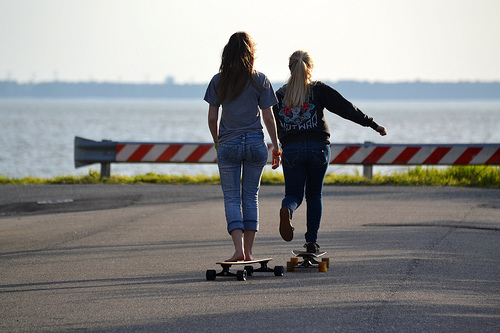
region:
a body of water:
[30, 54, 498, 189]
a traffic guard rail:
[62, 113, 494, 202]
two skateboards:
[200, 220, 410, 281]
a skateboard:
[190, 231, 284, 316]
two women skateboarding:
[190, 35, 411, 323]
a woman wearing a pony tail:
[282, 39, 350, 165]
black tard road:
[32, 182, 484, 332]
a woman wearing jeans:
[180, 25, 303, 285]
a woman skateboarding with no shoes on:
[183, 32, 280, 302]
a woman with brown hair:
[197, 42, 287, 159]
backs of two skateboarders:
[189, 29, 381, 279]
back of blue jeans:
[219, 129, 274, 240]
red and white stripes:
[360, 139, 465, 169]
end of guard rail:
[60, 129, 116, 174]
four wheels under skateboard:
[277, 255, 337, 277]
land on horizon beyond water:
[392, 74, 474, 106]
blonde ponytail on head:
[282, 59, 312, 114]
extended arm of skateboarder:
[332, 81, 396, 140]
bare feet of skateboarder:
[217, 226, 265, 267]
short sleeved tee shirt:
[204, 74, 279, 141]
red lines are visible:
[121, 131, 202, 216]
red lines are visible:
[136, 136, 191, 176]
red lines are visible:
[128, 88, 228, 183]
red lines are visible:
[102, 101, 214, 209]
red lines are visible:
[124, 124, 256, 256]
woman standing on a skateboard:
[204, 31, 280, 287]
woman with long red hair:
[199, 32, 281, 289]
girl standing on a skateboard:
[202, 27, 281, 284]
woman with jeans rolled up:
[201, 33, 278, 277]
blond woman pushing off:
[273, 45, 388, 272]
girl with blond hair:
[269, 45, 416, 281]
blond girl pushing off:
[274, 46, 389, 279]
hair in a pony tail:
[276, 44, 333, 126]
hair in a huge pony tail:
[203, 21, 269, 124]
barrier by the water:
[74, 128, 499, 183]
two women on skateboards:
[196, 26, 388, 281]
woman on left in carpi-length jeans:
[208, 125, 275, 285]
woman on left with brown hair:
[212, 31, 257, 107]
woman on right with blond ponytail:
[281, 45, 319, 117]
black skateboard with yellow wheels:
[281, 240, 333, 274]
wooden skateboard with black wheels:
[196, 247, 288, 287]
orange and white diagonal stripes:
[104, 132, 495, 170]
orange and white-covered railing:
[71, 137, 498, 181]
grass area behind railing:
[3, 162, 498, 190]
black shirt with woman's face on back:
[277, 83, 329, 135]